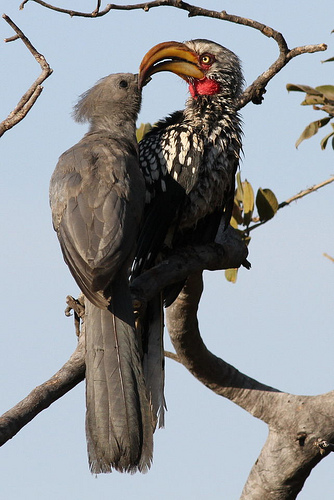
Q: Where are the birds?
A: On branches.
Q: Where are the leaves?
A: Next to the birds.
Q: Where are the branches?
A: On the tree.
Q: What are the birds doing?
A: Touching beaks.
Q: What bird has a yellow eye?
A: The right bird.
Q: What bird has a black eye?
A: The left bird.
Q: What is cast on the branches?
A: Shadows.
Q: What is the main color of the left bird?
A: Gray.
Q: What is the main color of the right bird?
A: Black.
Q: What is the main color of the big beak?
A: Yellow.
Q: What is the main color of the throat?
A: Red.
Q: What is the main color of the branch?
A: Brown.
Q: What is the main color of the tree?
A: Brown.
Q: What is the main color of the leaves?
A: Green.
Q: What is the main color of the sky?
A: Blue.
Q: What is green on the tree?
A: Leaves.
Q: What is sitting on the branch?
A: A bird,.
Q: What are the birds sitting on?
A: A large tree limb,.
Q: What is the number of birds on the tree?
A: Two.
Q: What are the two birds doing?
A: Sitting on a branch,.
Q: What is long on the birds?
A: Tail feathers.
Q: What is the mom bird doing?
A: Feeding her young.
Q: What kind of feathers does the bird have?
A: Black and white spotted.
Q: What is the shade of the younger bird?
A: Grey.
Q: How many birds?
A: Two.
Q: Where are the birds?
A: A tree.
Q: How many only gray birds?
A: One.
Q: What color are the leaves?
A: Green.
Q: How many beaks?
A: Two.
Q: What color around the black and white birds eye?
A: Red.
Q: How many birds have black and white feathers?
A: One.